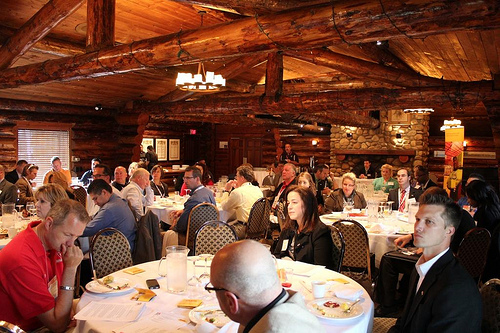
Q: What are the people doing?
A: Eating.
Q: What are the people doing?
A: Sitting.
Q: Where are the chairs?
A: Below the people.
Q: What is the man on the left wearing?
A: Red shirt.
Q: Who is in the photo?
A: Some people.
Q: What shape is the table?
A: Round.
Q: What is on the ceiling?
A: Wood log beams.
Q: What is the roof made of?
A: Wood.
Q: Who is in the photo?
A: Many people.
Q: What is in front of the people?
A: Table.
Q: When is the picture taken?
A: Day time.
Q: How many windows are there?
A: One.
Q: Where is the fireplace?
A: Background.